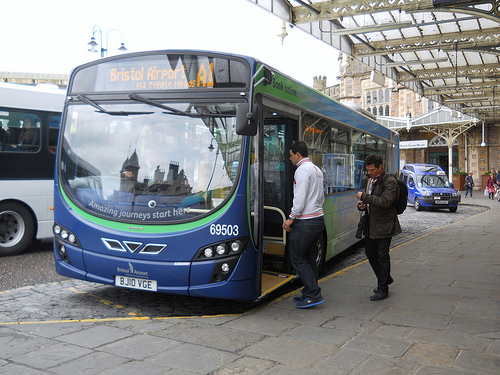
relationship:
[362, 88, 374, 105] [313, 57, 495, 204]
window of building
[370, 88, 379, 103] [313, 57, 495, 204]
window of building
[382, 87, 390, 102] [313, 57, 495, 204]
window of building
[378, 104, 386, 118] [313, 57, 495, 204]
window of building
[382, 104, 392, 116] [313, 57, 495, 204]
window of building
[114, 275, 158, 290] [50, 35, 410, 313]
license plate of bus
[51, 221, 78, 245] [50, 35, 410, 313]
headlights of bus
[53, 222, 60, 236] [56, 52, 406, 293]
headlight of bus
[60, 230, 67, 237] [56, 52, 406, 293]
headlight of bus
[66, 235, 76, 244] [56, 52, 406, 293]
headlight of bus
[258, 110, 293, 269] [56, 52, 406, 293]
doors of bus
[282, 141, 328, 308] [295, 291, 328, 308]
man wearing sneakers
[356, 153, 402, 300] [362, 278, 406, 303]
man wearing sneakers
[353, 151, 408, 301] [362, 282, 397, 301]
man wearing shoes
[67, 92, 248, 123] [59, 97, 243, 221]
windshield_wipers on window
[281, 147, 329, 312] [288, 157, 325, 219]
man wearing man sweater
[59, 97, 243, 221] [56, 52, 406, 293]
window of bus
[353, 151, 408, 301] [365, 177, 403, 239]
man wearing jacket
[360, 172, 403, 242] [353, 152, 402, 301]
jacket on man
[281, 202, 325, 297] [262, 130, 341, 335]
jeans on man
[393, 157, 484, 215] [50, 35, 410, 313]
car behind bus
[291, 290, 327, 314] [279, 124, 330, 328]
shoe on man